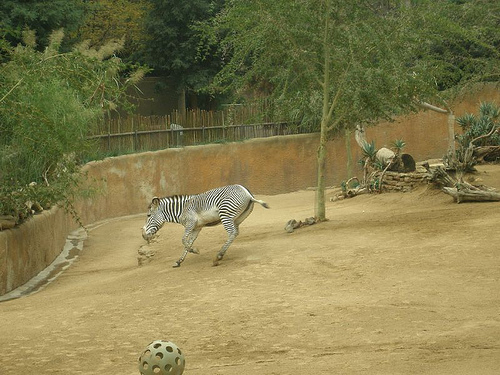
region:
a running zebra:
[140, 188, 259, 268]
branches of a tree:
[331, 48, 359, 128]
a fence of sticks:
[108, 116, 179, 142]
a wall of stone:
[102, 155, 209, 185]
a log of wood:
[377, 148, 390, 162]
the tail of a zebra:
[248, 193, 273, 213]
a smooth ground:
[266, 263, 458, 369]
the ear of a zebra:
[149, 196, 159, 206]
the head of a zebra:
[143, 197, 165, 236]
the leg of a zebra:
[213, 210, 234, 265]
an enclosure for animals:
[16, 130, 479, 349]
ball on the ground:
[128, 340, 195, 374]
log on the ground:
[438, 170, 498, 208]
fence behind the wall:
[86, 106, 278, 141]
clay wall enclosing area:
[90, 136, 370, 201]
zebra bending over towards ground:
[133, 178, 259, 284]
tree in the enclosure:
[184, 14, 431, 219]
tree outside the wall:
[0, 33, 103, 210]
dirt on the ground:
[258, 309, 458, 369]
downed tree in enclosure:
[458, 96, 499, 166]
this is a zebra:
[133, 175, 286, 265]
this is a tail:
[249, 185, 276, 214]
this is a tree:
[252, 17, 412, 122]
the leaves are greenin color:
[286, 23, 331, 91]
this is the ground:
[317, 244, 444, 336]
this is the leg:
[213, 217, 236, 269]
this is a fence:
[148, 115, 190, 144]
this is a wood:
[136, 120, 153, 144]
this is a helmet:
[136, 340, 178, 372]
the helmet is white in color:
[146, 343, 173, 362]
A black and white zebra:
[137, 171, 282, 268]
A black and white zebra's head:
[146, 189, 165, 239]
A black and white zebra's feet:
[182, 226, 204, 274]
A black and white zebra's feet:
[212, 210, 247, 263]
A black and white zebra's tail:
[246, 189, 269, 211]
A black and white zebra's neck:
[157, 196, 185, 229]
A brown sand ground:
[261, 249, 393, 357]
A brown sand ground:
[103, 283, 199, 333]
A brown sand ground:
[418, 216, 475, 333]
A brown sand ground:
[275, 231, 406, 288]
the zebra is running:
[122, 181, 270, 273]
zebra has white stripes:
[135, 179, 263, 259]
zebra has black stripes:
[138, 167, 278, 264]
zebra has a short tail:
[127, 173, 292, 281]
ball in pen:
[127, 332, 194, 372]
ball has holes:
[132, 337, 183, 374]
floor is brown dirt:
[262, 292, 422, 371]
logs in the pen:
[344, 107, 498, 208]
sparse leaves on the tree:
[247, 22, 400, 154]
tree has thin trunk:
[302, 92, 346, 229]